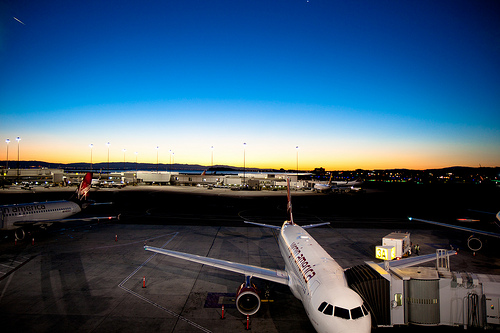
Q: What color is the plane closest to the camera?
A: White.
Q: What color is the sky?
A: Blue.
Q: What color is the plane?
A: White.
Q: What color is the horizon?
A: Yellow.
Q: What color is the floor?
A: Gray.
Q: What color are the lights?
A: White.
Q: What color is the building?
A: Gray.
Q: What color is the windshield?
A: Black.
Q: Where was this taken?
A: Airport.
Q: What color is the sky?
A: Blue.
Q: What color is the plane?
A: White.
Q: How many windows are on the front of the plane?
A: 5.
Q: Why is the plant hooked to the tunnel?
A: People are boarding.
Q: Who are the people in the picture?
A: Staff working on the runway.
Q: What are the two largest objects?
A: The airplanes.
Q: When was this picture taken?
A: At dusk.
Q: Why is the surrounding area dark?
A: It is almost night.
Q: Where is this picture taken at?
A: At an airport.